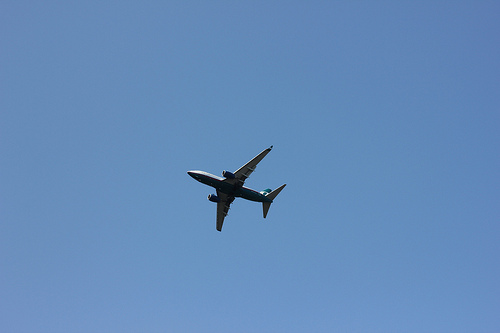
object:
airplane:
[186, 145, 288, 233]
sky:
[2, 2, 500, 332]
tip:
[185, 170, 201, 178]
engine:
[221, 170, 235, 180]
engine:
[207, 194, 220, 203]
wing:
[229, 145, 274, 184]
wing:
[215, 188, 236, 233]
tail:
[263, 183, 287, 218]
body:
[196, 172, 269, 203]